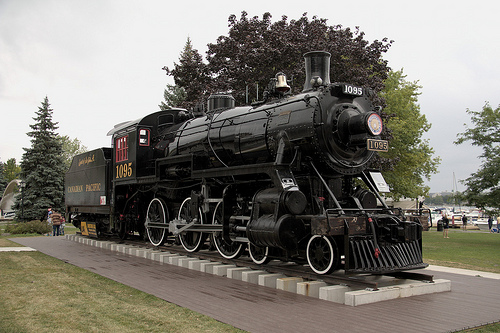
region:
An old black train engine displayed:
[61, 48, 436, 286]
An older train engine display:
[62, 48, 437, 286]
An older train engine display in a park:
[61, 47, 436, 286]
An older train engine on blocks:
[62, 48, 438, 284]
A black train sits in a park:
[62, 47, 437, 284]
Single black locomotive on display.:
[41, 42, 451, 302]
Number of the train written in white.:
[340, 76, 368, 97]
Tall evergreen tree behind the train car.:
[18, 89, 67, 248]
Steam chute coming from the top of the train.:
[296, 39, 337, 96]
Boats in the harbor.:
[423, 196, 488, 218]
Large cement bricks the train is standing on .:
[314, 277, 456, 311]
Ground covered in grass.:
[5, 264, 69, 323]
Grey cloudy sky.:
[2, 0, 159, 81]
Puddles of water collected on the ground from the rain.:
[77, 250, 277, 315]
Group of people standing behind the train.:
[40, 204, 67, 235]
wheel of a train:
[134, 178, 181, 258]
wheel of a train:
[176, 190, 219, 254]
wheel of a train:
[209, 188, 259, 256]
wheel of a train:
[252, 230, 286, 259]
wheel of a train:
[298, 231, 349, 275]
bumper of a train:
[337, 208, 434, 282]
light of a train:
[356, 103, 409, 145]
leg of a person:
[49, 220, 64, 233]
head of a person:
[42, 203, 54, 211]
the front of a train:
[313, 82, 412, 292]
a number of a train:
[334, 81, 367, 102]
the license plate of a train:
[362, 137, 408, 154]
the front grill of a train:
[358, 219, 433, 288]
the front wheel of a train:
[306, 234, 339, 277]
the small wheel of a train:
[246, 238, 281, 272]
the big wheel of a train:
[141, 199, 168, 239]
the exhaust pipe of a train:
[295, 41, 337, 92]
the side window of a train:
[109, 139, 140, 159]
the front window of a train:
[136, 128, 156, 146]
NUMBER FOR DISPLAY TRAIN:
[339, 79, 369, 98]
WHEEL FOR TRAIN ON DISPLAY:
[301, 231, 343, 276]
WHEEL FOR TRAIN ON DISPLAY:
[241, 234, 271, 266]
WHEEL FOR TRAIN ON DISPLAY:
[209, 201, 241, 259]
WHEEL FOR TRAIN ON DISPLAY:
[171, 194, 206, 253]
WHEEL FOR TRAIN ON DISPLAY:
[138, 196, 168, 248]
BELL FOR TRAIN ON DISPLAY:
[263, 70, 293, 98]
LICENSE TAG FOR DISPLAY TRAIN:
[359, 134, 399, 156]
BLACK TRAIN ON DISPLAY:
[66, 49, 435, 311]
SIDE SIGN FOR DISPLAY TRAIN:
[109, 134, 142, 182]